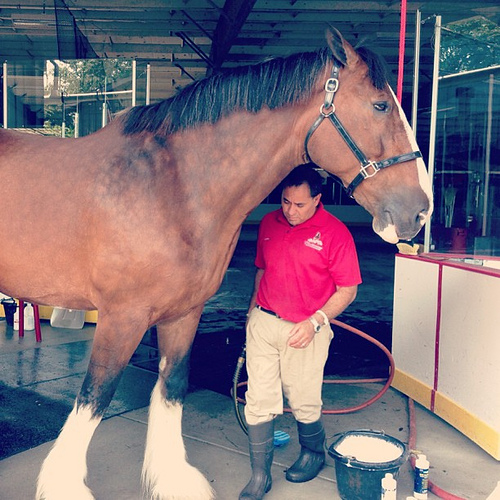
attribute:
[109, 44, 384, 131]
mane — short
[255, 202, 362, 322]
shirt — pink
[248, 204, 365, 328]
shirt — red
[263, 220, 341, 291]
shirt — red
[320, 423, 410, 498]
bucket — black, soapy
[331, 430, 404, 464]
liquid — white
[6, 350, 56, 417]
floor — grey, concrete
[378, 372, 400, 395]
hose — red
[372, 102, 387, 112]
horse eye — brown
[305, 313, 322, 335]
watch — white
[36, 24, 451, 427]
horse — brown, white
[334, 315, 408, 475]
hose — red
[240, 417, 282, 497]
rubber boots — black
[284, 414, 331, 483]
rubber boots — black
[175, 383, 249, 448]
floor — wet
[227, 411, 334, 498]
boots — black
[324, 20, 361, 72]
horses ear — one of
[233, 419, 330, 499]
boots — black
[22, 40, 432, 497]
horse — black, brown, tall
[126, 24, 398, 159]
mane — trimmed 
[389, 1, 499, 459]
partition — white, red, yellow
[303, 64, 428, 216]
bridal — black